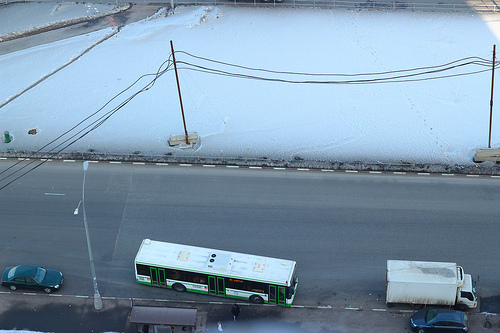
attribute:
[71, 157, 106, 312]
light pole — tall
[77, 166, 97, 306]
lamp — white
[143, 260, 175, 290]
doors — green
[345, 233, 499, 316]
truck — white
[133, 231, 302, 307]
bus — white, big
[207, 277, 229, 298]
doors — green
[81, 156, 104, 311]
street light — tall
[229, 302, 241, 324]
person — black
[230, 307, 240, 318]
jacket — black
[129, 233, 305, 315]
bus — long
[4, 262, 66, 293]
car — green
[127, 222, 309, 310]
bus — full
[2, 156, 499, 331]
pavement — black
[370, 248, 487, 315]
truck — white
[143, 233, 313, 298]
bus — white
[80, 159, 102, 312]
pole — gray